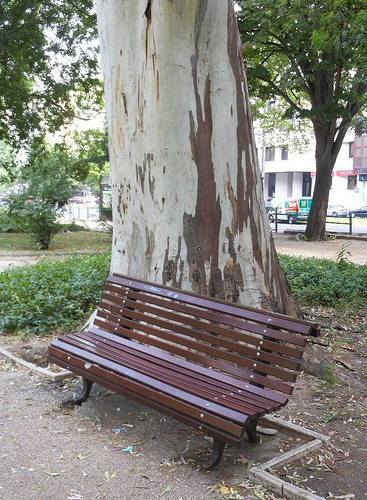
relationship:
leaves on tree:
[230, 0, 366, 154] [274, 40, 364, 251]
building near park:
[43, 113, 118, 232] [0, 0, 366, 498]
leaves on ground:
[215, 404, 360, 495] [2, 302, 366, 497]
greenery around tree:
[1, 242, 365, 341] [246, 4, 365, 305]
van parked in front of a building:
[267, 191, 326, 225] [249, 71, 363, 227]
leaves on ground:
[22, 260, 361, 357] [2, 354, 302, 498]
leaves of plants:
[25, 264, 86, 313] [335, 240, 355, 274]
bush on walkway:
[1, 183, 85, 250] [3, 335, 265, 497]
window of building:
[301, 174, 310, 195] [243, 107, 355, 237]